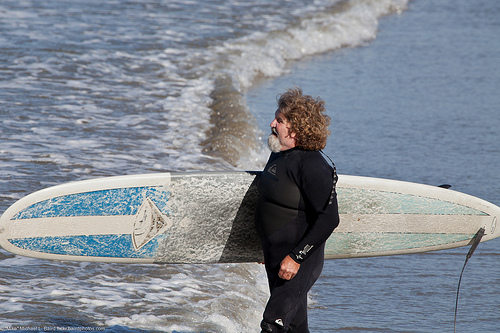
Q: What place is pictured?
A: It is an ocean.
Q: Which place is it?
A: It is an ocean.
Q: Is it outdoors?
A: Yes, it is outdoors.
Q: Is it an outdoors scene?
A: Yes, it is outdoors.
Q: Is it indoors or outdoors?
A: It is outdoors.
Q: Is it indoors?
A: No, it is outdoors.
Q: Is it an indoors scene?
A: No, it is outdoors.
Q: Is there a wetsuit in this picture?
A: Yes, there is a wetsuit.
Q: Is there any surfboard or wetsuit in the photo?
A: Yes, there is a wetsuit.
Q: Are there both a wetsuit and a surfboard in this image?
A: Yes, there are both a wetsuit and a surfboard.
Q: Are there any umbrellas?
A: No, there are no umbrellas.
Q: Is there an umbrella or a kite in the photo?
A: No, there are no umbrellas or kites.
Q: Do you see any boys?
A: No, there are no boys.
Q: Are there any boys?
A: No, there are no boys.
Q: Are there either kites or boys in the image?
A: No, there are no boys or kites.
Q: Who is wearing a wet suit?
A: The man is wearing a wet suit.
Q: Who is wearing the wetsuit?
A: The man is wearing a wet suit.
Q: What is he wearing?
A: The man is wearing a wetsuit.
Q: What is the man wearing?
A: The man is wearing a wetsuit.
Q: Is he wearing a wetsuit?
A: Yes, the man is wearing a wetsuit.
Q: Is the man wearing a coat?
A: No, the man is wearing a wetsuit.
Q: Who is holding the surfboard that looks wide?
A: The man is holding the surfboard.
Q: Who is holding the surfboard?
A: The man is holding the surfboard.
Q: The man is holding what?
A: The man is holding the surf board.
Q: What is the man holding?
A: The man is holding the surf board.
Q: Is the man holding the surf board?
A: Yes, the man is holding the surf board.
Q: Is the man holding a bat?
A: No, the man is holding the surf board.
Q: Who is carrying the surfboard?
A: The man is carrying the surfboard.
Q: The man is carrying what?
A: The man is carrying a surfboard.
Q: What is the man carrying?
A: The man is carrying a surfboard.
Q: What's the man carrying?
A: The man is carrying a surfboard.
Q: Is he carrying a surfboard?
A: Yes, the man is carrying a surfboard.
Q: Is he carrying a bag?
A: No, the man is carrying a surfboard.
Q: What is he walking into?
A: The man is walking into the ocean.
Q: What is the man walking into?
A: The man is walking into the ocean.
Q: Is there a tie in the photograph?
A: Yes, there is a tie.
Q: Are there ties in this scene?
A: Yes, there is a tie.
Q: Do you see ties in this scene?
A: Yes, there is a tie.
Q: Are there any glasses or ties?
A: Yes, there is a tie.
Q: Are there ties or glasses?
A: Yes, there is a tie.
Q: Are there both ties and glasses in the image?
A: No, there is a tie but no glasses.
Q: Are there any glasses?
A: No, there are no glasses.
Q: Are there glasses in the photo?
A: No, there are no glasses.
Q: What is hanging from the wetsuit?
A: The tie is hanging from the wetsuit.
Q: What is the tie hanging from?
A: The necktie is hanging from the wetsuit.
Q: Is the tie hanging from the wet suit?
A: Yes, the tie is hanging from the wet suit.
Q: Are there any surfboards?
A: Yes, there is a surfboard.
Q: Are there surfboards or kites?
A: Yes, there is a surfboard.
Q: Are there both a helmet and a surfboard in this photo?
A: No, there is a surfboard but no helmets.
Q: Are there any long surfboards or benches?
A: Yes, there is a long surfboard.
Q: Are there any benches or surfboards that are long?
A: Yes, the surfboard is long.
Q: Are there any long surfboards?
A: Yes, there is a long surfboard.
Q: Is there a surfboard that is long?
A: Yes, there is a surfboard that is long.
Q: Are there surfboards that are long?
A: Yes, there is a surfboard that is long.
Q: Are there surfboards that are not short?
A: Yes, there is a long surfboard.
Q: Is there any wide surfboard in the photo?
A: Yes, there is a wide surfboard.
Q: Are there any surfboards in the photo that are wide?
A: Yes, there is a surfboard that is wide.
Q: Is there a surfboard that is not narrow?
A: Yes, there is a wide surfboard.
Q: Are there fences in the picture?
A: No, there are no fences.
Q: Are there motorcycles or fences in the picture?
A: No, there are no fences or motorcycles.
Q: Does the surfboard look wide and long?
A: Yes, the surfboard is wide and long.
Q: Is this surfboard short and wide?
A: No, the surfboard is wide but long.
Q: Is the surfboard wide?
A: Yes, the surfboard is wide.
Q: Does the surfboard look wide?
A: Yes, the surfboard is wide.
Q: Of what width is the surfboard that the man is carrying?
A: The surfboard is wide.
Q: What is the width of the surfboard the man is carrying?
A: The surfboard is wide.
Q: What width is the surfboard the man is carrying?
A: The surfboard is wide.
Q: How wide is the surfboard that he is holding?
A: The surfboard is wide.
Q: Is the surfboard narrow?
A: No, the surfboard is wide.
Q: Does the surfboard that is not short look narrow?
A: No, the surfboard is wide.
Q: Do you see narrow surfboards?
A: No, there is a surfboard but it is wide.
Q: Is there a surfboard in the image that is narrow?
A: No, there is a surfboard but it is wide.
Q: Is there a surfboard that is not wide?
A: No, there is a surfboard but it is wide.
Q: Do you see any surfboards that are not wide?
A: No, there is a surfboard but it is wide.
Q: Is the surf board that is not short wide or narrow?
A: The surfboard is wide.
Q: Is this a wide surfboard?
A: Yes, this is a wide surfboard.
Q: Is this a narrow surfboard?
A: No, this is a wide surfboard.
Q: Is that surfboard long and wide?
A: Yes, the surfboard is long and wide.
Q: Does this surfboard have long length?
A: Yes, the surfboard is long.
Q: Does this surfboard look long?
A: Yes, the surfboard is long.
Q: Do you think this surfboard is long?
A: Yes, the surfboard is long.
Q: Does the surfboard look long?
A: Yes, the surfboard is long.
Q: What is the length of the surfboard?
A: The surfboard is long.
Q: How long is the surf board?
A: The surf board is long.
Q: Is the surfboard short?
A: No, the surfboard is long.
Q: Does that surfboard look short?
A: No, the surfboard is long.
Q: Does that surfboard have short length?
A: No, the surfboard is long.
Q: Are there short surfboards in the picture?
A: No, there is a surfboard but it is long.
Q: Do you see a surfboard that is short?
A: No, there is a surfboard but it is long.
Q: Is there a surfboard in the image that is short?
A: No, there is a surfboard but it is long.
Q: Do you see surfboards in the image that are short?
A: No, there is a surfboard but it is long.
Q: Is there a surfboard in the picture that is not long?
A: No, there is a surfboard but it is long.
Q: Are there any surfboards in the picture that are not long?
A: No, there is a surfboard but it is long.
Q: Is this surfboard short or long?
A: The surfboard is long.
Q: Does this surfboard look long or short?
A: The surfboard is long.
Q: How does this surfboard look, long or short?
A: The surfboard is long.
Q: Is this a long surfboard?
A: Yes, this is a long surfboard.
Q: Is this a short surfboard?
A: No, this is a long surfboard.